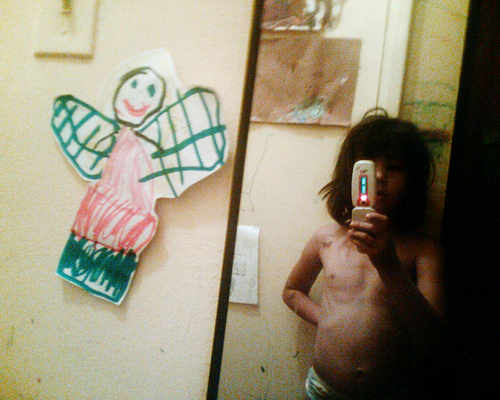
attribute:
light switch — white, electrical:
[34, 3, 99, 58]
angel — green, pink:
[47, 64, 227, 190]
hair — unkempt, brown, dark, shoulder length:
[365, 117, 413, 151]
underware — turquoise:
[308, 372, 327, 400]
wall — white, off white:
[132, 17, 204, 53]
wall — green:
[422, 97, 459, 122]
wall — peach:
[415, 26, 454, 51]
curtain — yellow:
[416, 1, 464, 73]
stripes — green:
[402, 100, 452, 115]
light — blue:
[361, 176, 367, 194]